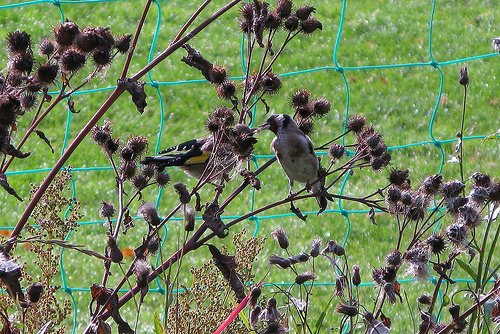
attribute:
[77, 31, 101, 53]
flower — purple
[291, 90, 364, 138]
flower — purple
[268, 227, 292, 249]
ball — purple, small, prickly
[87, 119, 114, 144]
flower — purple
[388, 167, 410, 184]
flower — purple 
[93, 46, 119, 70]
ball — small, prickly, purple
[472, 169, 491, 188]
ball — purple, prickly, small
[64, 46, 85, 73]
flower — purple 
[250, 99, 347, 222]
bird — small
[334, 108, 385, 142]
ball — small, prickly, purple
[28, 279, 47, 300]
ball — small, prickly, purple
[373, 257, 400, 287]
ball — prickly, small, purple